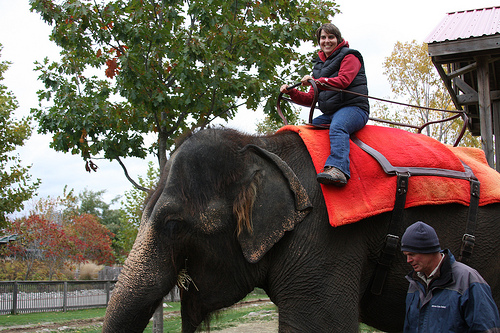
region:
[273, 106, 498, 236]
a bright orange blanket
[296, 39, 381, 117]
a black woman's vest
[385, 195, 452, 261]
a blue men's hat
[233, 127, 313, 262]
the elephant's right ear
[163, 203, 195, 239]
the elephant's right eye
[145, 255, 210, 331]
an elephants open mouth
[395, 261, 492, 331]
a man's blue jacket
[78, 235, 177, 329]
the elephants large trunk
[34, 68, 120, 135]
these are green leaves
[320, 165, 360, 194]
the woman's right shoe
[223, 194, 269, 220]
brown spot on elephant's ear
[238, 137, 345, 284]
floppy black elephant ear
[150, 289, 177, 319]
small white spot on ground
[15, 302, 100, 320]
green manicured grass in the back ground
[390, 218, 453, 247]
blue cap on man's head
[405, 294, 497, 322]
white words on man's jacket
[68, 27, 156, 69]
yellow leaves on green tree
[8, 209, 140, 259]
large tree with cranberry leaves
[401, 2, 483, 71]
pink roof on black building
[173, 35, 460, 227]
man riding black elephant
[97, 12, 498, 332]
Woman is on top of a elephant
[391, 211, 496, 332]
Man is in the foreground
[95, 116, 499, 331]
Elephant is dark gray in color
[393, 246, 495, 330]
Man is wearing a blue jacket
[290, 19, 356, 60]
Woman has short hair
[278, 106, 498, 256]
Woman is sitting on top of a red carpet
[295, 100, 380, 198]
Woman's Jeans are blue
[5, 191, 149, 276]
Trees are in the background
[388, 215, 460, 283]
Man is wearing a gray knit cap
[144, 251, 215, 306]
Elephant has food in its mouth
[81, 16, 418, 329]
man riding elephant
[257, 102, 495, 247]
elephant with red blanket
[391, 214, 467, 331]
man in blue hat with black stripe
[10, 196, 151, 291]
red colored leaves on trees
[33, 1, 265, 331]
green tree behind elephant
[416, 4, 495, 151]
building with red roof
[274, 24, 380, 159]
man in black vest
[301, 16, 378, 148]
man in red shirt and black vest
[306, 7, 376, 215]
man in blue jeans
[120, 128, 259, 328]
elephant with hay in it's mouth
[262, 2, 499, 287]
person riding on an elephant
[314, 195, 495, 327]
man standing next to elephant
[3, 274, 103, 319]
fence next to grass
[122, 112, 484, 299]
elephant with orange saddle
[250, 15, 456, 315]
person wearing black vest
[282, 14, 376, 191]
person wearing blue jeans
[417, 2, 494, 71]
red roof on wooden beams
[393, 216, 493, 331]
mean wearing blue beanie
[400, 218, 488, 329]
man wearing blue jacket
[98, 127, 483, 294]
elephant walking